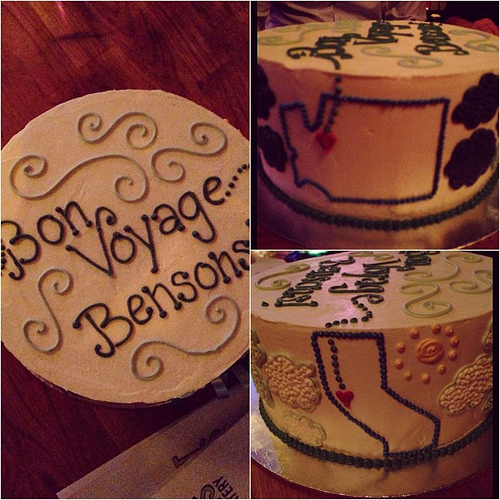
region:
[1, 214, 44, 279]
black letter on cake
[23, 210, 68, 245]
black letter on cake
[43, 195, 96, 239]
black letter on cake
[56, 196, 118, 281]
black letter on cake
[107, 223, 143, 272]
black letter on cake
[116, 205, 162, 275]
black letter on cake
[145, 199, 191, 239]
black letter on cake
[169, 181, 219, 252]
black letter on cake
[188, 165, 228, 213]
black letter on cake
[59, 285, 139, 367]
black letter on cake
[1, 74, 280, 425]
this is the top of the cake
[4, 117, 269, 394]
the cake has words on it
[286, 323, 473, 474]
a cake decoration shaped like California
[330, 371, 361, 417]
a frosting heart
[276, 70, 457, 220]
this is Washington state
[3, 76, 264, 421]
the cake has white frosting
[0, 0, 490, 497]
this is a going away cake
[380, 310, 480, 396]
this is the sun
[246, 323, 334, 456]
these decorations are shaped like clouds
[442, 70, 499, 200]
these clouds are dark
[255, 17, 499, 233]
side shot of decorated cake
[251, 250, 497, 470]
reverse side shot of cake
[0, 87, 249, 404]
top view of cake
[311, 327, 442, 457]
california drawn in frosting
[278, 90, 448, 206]
state of Washington in frosting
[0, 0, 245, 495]
A wooden table top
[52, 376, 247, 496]
a couple menus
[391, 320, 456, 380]
The sun drawn in frosting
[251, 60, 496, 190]
rain clouds drawn in frosting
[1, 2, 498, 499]
Three views of a farewell cake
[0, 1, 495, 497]
three separate pictures of decorated cake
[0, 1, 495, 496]
three photos of the same cake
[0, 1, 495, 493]
three photographs of one cake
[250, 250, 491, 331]
the top of a decorated cake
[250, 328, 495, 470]
decor on the side of the cake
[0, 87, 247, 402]
"Bon Voyage Bensons' on the top of the cake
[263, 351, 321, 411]
a flower frosting decor on the side of the cake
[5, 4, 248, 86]
a brown wooden tabletop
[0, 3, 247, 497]
a bakery baked cake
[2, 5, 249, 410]
a frosted decorative cake on a wooden table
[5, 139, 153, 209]
design on party cake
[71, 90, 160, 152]
design on party cake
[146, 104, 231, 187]
design on party cake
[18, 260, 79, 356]
design on party cake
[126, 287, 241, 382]
design on party cake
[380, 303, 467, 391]
design on party cake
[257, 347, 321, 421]
design on party cake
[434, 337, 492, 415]
design on party cake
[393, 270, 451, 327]
design on party cake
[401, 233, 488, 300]
design on party cake